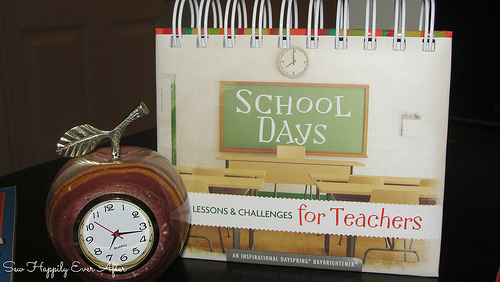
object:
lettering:
[0, 260, 129, 280]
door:
[20, 21, 94, 166]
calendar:
[153, 0, 454, 278]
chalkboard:
[217, 79, 371, 158]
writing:
[235, 89, 352, 146]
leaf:
[54, 122, 113, 158]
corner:
[0, 184, 18, 282]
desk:
[0, 127, 500, 282]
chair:
[272, 144, 308, 200]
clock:
[276, 45, 310, 79]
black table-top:
[0, 127, 500, 282]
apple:
[44, 101, 192, 282]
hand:
[108, 228, 120, 251]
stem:
[106, 101, 150, 158]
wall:
[156, 35, 453, 180]